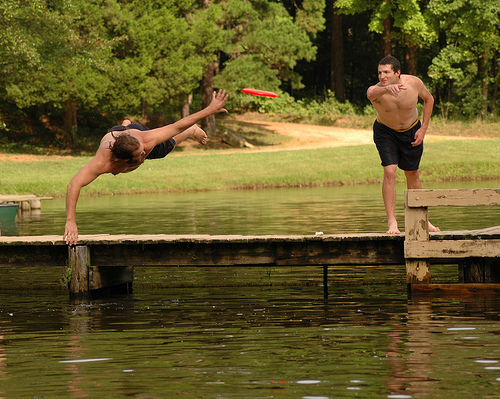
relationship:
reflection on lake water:
[340, 298, 472, 395] [0, 180, 500, 399]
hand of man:
[416, 79, 440, 154] [341, 49, 488, 305]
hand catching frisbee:
[209, 88, 230, 113] [239, 88, 284, 100]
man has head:
[57, 76, 235, 249] [109, 134, 147, 166]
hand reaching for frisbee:
[208, 86, 231, 117] [237, 75, 287, 112]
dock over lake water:
[263, 232, 378, 276] [0, 180, 500, 399]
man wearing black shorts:
[366, 55, 446, 238] [365, 111, 430, 177]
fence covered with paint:
[404, 188, 500, 311] [408, 187, 498, 278]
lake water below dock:
[0, 180, 500, 399] [3, 226, 498, 267]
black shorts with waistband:
[372, 117, 424, 172] [370, 116, 422, 136]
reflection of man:
[388, 298, 436, 395] [366, 55, 446, 238]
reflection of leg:
[388, 298, 436, 395] [380, 165, 400, 235]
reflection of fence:
[388, 298, 436, 395] [404, 188, 500, 311]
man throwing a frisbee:
[364, 54, 441, 235] [239, 82, 276, 99]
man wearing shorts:
[366, 55, 446, 238] [363, 110, 461, 195]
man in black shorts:
[57, 76, 235, 249] [108, 122, 177, 159]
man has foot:
[366, 55, 446, 238] [383, 225, 403, 235]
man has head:
[57, 76, 235, 249] [104, 133, 154, 164]